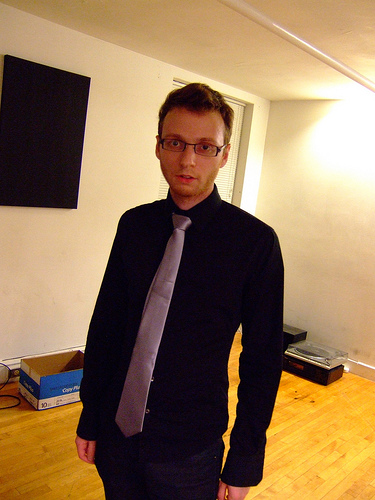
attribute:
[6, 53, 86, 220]
rectangle — black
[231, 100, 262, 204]
door — white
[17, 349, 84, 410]
box — blue, white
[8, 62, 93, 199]
board — black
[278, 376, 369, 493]
floor — light brown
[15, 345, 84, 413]
box — blue, white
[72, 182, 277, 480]
shirt — black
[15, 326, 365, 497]
floors — hardwooden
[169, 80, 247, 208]
window — white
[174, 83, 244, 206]
blinds — white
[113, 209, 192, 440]
tie — purple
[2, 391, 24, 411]
cord — black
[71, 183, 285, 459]
shirt — black